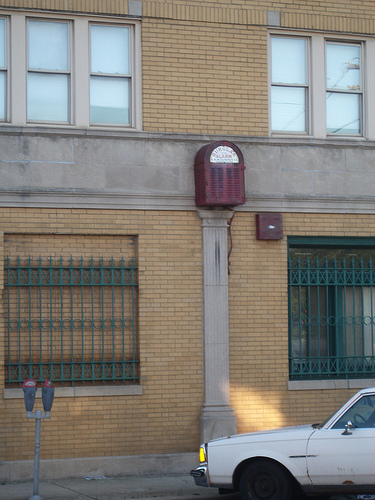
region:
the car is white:
[201, 374, 373, 477]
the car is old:
[203, 381, 373, 488]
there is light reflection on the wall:
[229, 384, 280, 424]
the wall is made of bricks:
[156, 348, 200, 442]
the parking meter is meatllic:
[15, 377, 55, 494]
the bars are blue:
[293, 300, 373, 376]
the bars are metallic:
[292, 300, 371, 378]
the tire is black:
[240, 464, 282, 499]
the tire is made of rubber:
[246, 464, 294, 497]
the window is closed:
[8, 265, 139, 386]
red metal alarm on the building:
[193, 132, 255, 210]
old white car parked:
[192, 369, 372, 497]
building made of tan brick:
[7, 209, 373, 465]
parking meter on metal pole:
[17, 368, 56, 497]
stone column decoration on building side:
[185, 206, 239, 449]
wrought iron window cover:
[291, 251, 368, 377]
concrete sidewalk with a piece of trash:
[7, 472, 191, 498]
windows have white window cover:
[269, 115, 362, 139]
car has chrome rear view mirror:
[341, 410, 368, 445]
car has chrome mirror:
[195, 440, 213, 496]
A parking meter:
[17, 368, 72, 499]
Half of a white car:
[172, 341, 373, 498]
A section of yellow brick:
[154, 251, 195, 404]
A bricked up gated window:
[4, 237, 143, 381]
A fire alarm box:
[250, 202, 291, 248]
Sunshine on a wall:
[212, 372, 291, 426]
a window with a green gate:
[278, 251, 373, 382]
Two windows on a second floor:
[241, 20, 373, 158]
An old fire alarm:
[182, 128, 253, 218]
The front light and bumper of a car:
[179, 433, 222, 489]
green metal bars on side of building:
[2, 258, 140, 380]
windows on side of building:
[0, 17, 141, 125]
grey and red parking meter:
[22, 376, 36, 415]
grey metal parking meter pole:
[27, 413, 46, 498]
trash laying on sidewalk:
[83, 458, 120, 487]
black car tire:
[234, 462, 296, 498]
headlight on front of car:
[193, 441, 209, 464]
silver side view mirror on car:
[341, 419, 357, 440]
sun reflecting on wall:
[210, 375, 285, 428]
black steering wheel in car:
[351, 409, 370, 430]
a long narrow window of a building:
[86, 20, 137, 127]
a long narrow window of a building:
[23, 13, 76, 127]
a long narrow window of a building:
[268, 31, 314, 137]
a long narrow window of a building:
[322, 31, 365, 139]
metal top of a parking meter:
[25, 378, 37, 411]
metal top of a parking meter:
[43, 379, 57, 410]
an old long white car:
[193, 384, 373, 494]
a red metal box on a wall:
[256, 210, 282, 239]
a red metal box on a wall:
[197, 138, 248, 206]